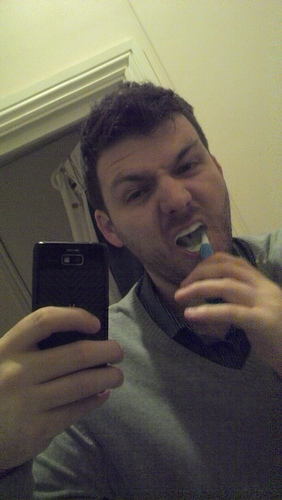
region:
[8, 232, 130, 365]
Small black cellular phone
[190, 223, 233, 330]
Blue and white toothbrush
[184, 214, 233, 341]
Plastic white and blue toothbrush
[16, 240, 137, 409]
Black cell phone made by Motorola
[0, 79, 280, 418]
Person brushing their teeth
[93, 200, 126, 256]
Medium sized human ear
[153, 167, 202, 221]
Medium sized human nose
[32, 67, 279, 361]
Person with toothbrush in their mouth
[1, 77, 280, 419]
Person taking a photo of themselves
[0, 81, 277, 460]
Person with brown hair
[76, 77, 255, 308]
man brushing teeth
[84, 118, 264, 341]
man holding tooth brush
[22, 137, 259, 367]
man taking selfie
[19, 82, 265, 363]
man taking photo on cell phone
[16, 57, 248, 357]
man taking selfie while brushing teeth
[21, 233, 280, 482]
man wearing grey v-neck sweater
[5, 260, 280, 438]
grey sweater and collared shirt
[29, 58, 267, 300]
brunette white man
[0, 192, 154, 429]
man holding black cell phone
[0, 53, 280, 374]
man getting ready in bathroom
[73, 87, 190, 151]
Brown hair of man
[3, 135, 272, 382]
Man holding a phone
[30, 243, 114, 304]
Phone with a camera on it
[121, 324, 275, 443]
Gray shirt on man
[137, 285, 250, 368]
Dress shirt under sweater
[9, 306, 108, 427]
Hand holding phone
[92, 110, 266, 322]
Man brushing teeth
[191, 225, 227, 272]
Blue and white toothbrush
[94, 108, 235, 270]
Angry expression on face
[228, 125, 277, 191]
White wall behind man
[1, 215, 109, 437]
Hand holding a cell phone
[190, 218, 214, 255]
Blue and white toothbrush.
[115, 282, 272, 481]
V-neck sweater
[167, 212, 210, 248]
Toothpaste foam in mouth.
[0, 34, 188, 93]
Wooden frame of door.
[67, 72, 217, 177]
Man's with dark brown curly hair.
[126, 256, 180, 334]
Oxford style shirt under V-neck sweater.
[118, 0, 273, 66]
Cream-colored bathroom wall.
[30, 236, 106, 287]
Black Cell phone with camera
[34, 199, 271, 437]
Man's hands holding cell phone and toothbrush.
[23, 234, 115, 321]
a cell phone in the man's hand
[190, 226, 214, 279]
a toothbrush being used by the man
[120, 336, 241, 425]
a grey pullover sweater being worn by the man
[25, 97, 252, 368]
a guy taking a selfie while brushing his teeth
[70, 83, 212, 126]
the man's short hair style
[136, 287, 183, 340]
a collared undershirt being worn by the man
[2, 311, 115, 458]
the man's hand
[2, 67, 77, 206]
a doorway behind the man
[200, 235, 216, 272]
a blue and white tooth brush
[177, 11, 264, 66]
white walls behind the man